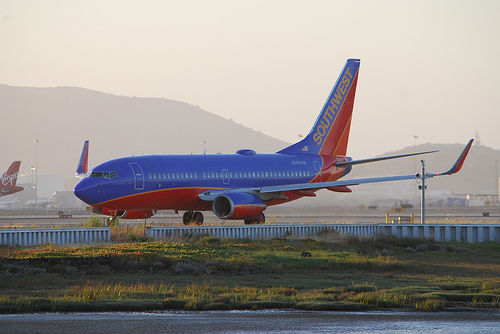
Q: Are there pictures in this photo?
A: No, there are no pictures.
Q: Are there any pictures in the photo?
A: No, there are no pictures.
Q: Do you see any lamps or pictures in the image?
A: No, there are no pictures or lamps.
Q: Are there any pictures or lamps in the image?
A: No, there are no pictures or lamps.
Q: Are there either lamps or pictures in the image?
A: No, there are no pictures or lamps.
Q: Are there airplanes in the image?
A: Yes, there is an airplane.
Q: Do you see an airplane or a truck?
A: Yes, there is an airplane.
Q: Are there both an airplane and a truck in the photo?
A: No, there is an airplane but no trucks.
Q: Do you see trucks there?
A: No, there are no trucks.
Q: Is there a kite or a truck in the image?
A: No, there are no trucks or kites.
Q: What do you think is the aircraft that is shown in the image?
A: The aircraft is an airplane.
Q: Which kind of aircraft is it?
A: The aircraft is an airplane.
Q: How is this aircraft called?
A: This is an airplane.